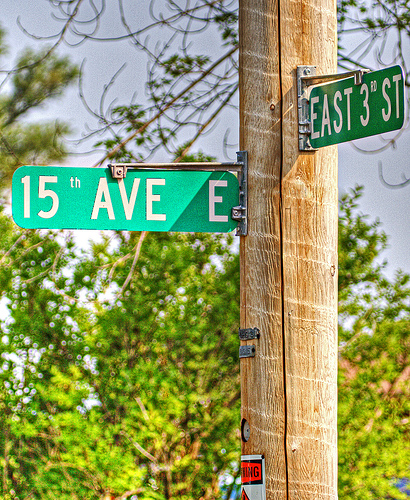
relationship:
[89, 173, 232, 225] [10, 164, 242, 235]
ave e written on a sign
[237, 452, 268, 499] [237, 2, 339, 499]
sign connected to pole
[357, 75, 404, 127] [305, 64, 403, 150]
3rd st written on a sign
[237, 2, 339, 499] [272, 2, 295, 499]
pole has a crack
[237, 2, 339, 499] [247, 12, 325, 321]
pole has scratches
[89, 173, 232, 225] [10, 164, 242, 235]
ave e written on sign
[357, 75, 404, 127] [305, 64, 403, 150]
3rd st written on sign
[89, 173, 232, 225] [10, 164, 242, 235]
ave e on sign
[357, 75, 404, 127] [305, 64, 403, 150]
3rd st on sign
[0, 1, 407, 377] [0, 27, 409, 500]
sky behind trees